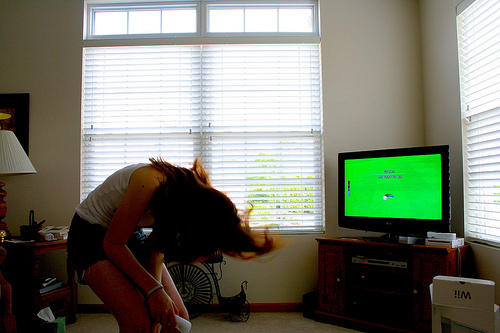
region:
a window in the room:
[91, 45, 316, 223]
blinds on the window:
[85, 50, 316, 230]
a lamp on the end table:
[0, 125, 40, 246]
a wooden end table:
[5, 215, 86, 315]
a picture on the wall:
[1, 90, 26, 155]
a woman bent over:
[71, 165, 251, 325]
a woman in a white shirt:
[71, 160, 237, 330]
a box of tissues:
[35, 305, 70, 325]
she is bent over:
[52, 138, 292, 329]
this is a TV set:
[316, 125, 484, 229]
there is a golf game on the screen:
[330, 133, 476, 235]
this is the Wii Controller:
[155, 300, 207, 331]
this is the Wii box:
[418, 262, 498, 331]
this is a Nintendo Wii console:
[413, 227, 472, 257]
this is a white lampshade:
[1, 123, 47, 187]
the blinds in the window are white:
[75, 28, 337, 226]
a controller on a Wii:
[420, 223, 465, 243]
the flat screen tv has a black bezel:
[322, 133, 496, 239]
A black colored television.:
[335, 143, 454, 239]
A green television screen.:
[342, 151, 442, 218]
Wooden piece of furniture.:
[308, 235, 467, 330]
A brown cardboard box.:
[429, 275, 499, 330]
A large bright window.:
[79, 0, 327, 235]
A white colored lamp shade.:
[0, 128, 37, 172]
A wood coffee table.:
[4, 231, 78, 323]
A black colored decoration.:
[168, 255, 252, 322]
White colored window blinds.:
[454, 0, 499, 245]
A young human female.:
[67, 152, 295, 332]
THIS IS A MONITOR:
[325, 120, 470, 242]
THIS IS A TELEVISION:
[317, 125, 463, 240]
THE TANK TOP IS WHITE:
[65, 155, 172, 242]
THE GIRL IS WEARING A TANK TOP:
[62, 150, 167, 242]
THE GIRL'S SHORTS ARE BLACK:
[56, 207, 167, 293]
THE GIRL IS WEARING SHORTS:
[57, 205, 167, 283]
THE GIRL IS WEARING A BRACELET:
[140, 280, 173, 307]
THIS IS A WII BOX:
[430, 266, 498, 327]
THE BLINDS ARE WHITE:
[67, 35, 329, 236]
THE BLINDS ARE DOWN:
[78, 35, 333, 235]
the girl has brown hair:
[111, 145, 286, 278]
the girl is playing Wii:
[12, 120, 301, 329]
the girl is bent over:
[28, 140, 283, 327]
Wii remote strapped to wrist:
[134, 277, 204, 327]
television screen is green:
[325, 135, 479, 242]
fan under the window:
[132, 251, 302, 331]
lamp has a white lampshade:
[0, 122, 52, 234]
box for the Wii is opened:
[414, 272, 499, 331]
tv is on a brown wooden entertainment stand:
[289, 222, 479, 323]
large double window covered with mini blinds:
[76, 37, 333, 238]